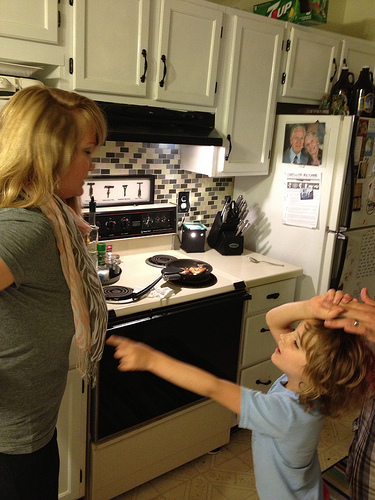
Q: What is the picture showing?
A: It is showing a kitchen.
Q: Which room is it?
A: It is a kitchen.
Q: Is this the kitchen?
A: Yes, it is the kitchen.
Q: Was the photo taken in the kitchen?
A: Yes, it was taken in the kitchen.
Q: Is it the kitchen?
A: Yes, it is the kitchen.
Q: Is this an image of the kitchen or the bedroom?
A: It is showing the kitchen.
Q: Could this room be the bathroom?
A: No, it is the kitchen.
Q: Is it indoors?
A: Yes, it is indoors.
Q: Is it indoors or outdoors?
A: It is indoors.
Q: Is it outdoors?
A: No, it is indoors.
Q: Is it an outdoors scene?
A: No, it is indoors.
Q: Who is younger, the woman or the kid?
A: The kid is younger than the woman.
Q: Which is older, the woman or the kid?
A: The woman is older than the kid.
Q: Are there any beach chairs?
A: No, there are no beach chairs.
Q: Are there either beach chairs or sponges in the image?
A: No, there are no beach chairs or sponges.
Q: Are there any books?
A: No, there are no books.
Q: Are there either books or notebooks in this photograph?
A: No, there are no books or notebooks.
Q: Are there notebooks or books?
A: No, there are no books or notebooks.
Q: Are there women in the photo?
A: Yes, there is a woman.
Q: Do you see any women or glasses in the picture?
A: Yes, there is a woman.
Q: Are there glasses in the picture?
A: No, there are no glasses.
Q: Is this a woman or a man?
A: This is a woman.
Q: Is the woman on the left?
A: Yes, the woman is on the left of the image.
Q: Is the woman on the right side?
A: No, the woman is on the left of the image.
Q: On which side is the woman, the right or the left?
A: The woman is on the left of the image.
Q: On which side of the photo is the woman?
A: The woman is on the left of the image.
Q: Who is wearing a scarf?
A: The woman is wearing a scarf.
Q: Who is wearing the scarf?
A: The woman is wearing a scarf.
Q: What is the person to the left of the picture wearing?
A: The woman is wearing a scarf.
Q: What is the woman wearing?
A: The woman is wearing a scarf.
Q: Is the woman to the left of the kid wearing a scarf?
A: Yes, the woman is wearing a scarf.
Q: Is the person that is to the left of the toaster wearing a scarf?
A: Yes, the woman is wearing a scarf.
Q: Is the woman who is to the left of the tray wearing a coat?
A: No, the woman is wearing a scarf.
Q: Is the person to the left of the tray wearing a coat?
A: No, the woman is wearing a scarf.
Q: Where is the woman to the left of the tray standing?
A: The woman is standing in the kitchen.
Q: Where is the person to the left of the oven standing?
A: The woman is standing in the kitchen.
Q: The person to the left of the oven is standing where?
A: The woman is standing in the kitchen.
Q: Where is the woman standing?
A: The woman is standing in the kitchen.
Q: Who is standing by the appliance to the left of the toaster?
A: The woman is standing by the oven.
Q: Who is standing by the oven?
A: The woman is standing by the oven.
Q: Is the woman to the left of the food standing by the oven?
A: Yes, the woman is standing by the oven.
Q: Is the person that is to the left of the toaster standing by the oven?
A: Yes, the woman is standing by the oven.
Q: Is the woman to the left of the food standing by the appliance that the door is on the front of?
A: Yes, the woman is standing by the oven.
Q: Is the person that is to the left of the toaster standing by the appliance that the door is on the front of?
A: Yes, the woman is standing by the oven.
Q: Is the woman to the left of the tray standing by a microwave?
A: No, the woman is standing by the oven.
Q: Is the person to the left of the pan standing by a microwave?
A: No, the woman is standing by the oven.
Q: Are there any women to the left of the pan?
A: Yes, there is a woman to the left of the pan.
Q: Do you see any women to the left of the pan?
A: Yes, there is a woman to the left of the pan.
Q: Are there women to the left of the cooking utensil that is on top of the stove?
A: Yes, there is a woman to the left of the pan.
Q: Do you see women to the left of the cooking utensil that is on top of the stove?
A: Yes, there is a woman to the left of the pan.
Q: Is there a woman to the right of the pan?
A: No, the woman is to the left of the pan.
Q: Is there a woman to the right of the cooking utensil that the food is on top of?
A: No, the woman is to the left of the pan.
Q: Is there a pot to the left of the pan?
A: No, there is a woman to the left of the pan.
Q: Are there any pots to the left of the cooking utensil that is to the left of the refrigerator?
A: No, there is a woman to the left of the pan.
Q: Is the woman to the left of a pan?
A: Yes, the woman is to the left of a pan.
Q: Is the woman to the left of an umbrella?
A: No, the woman is to the left of a pan.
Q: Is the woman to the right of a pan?
A: No, the woman is to the left of a pan.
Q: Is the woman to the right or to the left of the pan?
A: The woman is to the left of the pan.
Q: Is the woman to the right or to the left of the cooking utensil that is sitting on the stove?
A: The woman is to the left of the pan.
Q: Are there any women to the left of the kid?
A: Yes, there is a woman to the left of the kid.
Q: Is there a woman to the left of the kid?
A: Yes, there is a woman to the left of the kid.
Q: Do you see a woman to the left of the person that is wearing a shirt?
A: Yes, there is a woman to the left of the kid.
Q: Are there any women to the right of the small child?
A: No, the woman is to the left of the kid.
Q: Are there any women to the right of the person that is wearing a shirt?
A: No, the woman is to the left of the kid.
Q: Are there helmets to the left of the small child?
A: No, there is a woman to the left of the child.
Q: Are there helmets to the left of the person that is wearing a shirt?
A: No, there is a woman to the left of the child.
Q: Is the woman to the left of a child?
A: Yes, the woman is to the left of a child.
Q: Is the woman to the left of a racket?
A: No, the woman is to the left of a child.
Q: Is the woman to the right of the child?
A: No, the woman is to the left of the child.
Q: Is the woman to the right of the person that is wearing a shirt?
A: No, the woman is to the left of the child.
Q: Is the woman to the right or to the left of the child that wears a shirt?
A: The woman is to the left of the child.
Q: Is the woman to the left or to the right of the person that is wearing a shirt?
A: The woman is to the left of the child.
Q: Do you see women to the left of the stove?
A: Yes, there is a woman to the left of the stove.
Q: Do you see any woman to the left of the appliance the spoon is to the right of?
A: Yes, there is a woman to the left of the stove.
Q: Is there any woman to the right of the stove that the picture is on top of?
A: No, the woman is to the left of the stove.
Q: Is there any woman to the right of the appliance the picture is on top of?
A: No, the woman is to the left of the stove.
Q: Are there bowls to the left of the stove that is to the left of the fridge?
A: No, there is a woman to the left of the stove.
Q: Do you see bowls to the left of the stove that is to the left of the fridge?
A: No, there is a woman to the left of the stove.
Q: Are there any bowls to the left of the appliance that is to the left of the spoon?
A: No, there is a woman to the left of the stove.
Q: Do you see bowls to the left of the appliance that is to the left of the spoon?
A: No, there is a woman to the left of the stove.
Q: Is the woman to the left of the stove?
A: Yes, the woman is to the left of the stove.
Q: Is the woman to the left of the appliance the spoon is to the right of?
A: Yes, the woman is to the left of the stove.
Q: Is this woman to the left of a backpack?
A: No, the woman is to the left of the stove.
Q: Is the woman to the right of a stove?
A: No, the woman is to the left of a stove.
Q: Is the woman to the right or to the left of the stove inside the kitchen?
A: The woman is to the left of the stove.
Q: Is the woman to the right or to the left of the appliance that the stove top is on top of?
A: The woman is to the left of the stove.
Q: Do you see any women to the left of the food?
A: Yes, there is a woman to the left of the food.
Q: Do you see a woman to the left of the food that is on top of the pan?
A: Yes, there is a woman to the left of the food.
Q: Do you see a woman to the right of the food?
A: No, the woman is to the left of the food.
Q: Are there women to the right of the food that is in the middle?
A: No, the woman is to the left of the food.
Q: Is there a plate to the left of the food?
A: No, there is a woman to the left of the food.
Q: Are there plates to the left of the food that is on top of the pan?
A: No, there is a woman to the left of the food.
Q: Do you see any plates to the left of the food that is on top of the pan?
A: No, there is a woman to the left of the food.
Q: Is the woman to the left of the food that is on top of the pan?
A: Yes, the woman is to the left of the food.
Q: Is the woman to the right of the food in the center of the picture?
A: No, the woman is to the left of the food.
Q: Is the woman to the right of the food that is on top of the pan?
A: No, the woman is to the left of the food.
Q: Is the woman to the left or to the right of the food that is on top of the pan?
A: The woman is to the left of the food.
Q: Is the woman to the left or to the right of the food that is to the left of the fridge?
A: The woman is to the left of the food.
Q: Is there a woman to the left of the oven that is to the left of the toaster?
A: Yes, there is a woman to the left of the oven.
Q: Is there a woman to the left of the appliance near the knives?
A: Yes, there is a woman to the left of the oven.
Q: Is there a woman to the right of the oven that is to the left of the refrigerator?
A: No, the woman is to the left of the oven.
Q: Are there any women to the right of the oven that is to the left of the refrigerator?
A: No, the woman is to the left of the oven.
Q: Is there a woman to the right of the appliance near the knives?
A: No, the woman is to the left of the oven.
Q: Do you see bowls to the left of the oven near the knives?
A: No, there is a woman to the left of the oven.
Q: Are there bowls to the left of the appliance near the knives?
A: No, there is a woman to the left of the oven.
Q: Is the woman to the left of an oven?
A: Yes, the woman is to the left of an oven.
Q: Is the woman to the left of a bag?
A: No, the woman is to the left of an oven.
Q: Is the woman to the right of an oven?
A: No, the woman is to the left of an oven.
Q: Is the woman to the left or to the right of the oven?
A: The woman is to the left of the oven.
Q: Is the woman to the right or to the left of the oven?
A: The woman is to the left of the oven.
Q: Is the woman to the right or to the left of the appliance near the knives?
A: The woman is to the left of the oven.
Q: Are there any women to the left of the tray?
A: Yes, there is a woman to the left of the tray.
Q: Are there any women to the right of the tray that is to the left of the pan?
A: No, the woman is to the left of the tray.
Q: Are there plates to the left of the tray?
A: No, there is a woman to the left of the tray.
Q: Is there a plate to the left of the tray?
A: No, there is a woman to the left of the tray.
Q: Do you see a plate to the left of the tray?
A: No, there is a woman to the left of the tray.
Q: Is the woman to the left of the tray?
A: Yes, the woman is to the left of the tray.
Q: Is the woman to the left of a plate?
A: No, the woman is to the left of the tray.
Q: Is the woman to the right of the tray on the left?
A: No, the woman is to the left of the tray.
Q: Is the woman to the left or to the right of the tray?
A: The woman is to the left of the tray.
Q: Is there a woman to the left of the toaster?
A: Yes, there is a woman to the left of the toaster.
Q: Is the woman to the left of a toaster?
A: Yes, the woman is to the left of a toaster.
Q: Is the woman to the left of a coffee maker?
A: No, the woman is to the left of a toaster.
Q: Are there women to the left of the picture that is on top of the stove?
A: Yes, there is a woman to the left of the picture.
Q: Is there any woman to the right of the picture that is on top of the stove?
A: No, the woman is to the left of the picture.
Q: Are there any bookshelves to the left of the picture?
A: No, there is a woman to the left of the picture.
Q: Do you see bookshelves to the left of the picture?
A: No, there is a woman to the left of the picture.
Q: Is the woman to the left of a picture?
A: Yes, the woman is to the left of a picture.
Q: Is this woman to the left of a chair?
A: No, the woman is to the left of a picture.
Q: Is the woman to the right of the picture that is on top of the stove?
A: No, the woman is to the left of the picture.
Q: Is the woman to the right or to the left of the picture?
A: The woman is to the left of the picture.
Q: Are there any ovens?
A: Yes, there is an oven.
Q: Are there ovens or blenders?
A: Yes, there is an oven.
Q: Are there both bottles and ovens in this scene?
A: Yes, there are both an oven and a bottle.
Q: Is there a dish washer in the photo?
A: No, there are no dishwashers.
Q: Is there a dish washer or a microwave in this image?
A: No, there are no dishwashers or microwaves.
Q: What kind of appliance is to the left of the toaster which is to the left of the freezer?
A: The appliance is an oven.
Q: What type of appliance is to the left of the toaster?
A: The appliance is an oven.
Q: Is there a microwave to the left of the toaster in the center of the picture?
A: No, there is an oven to the left of the toaster.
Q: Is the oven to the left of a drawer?
A: No, the oven is to the left of the toaster.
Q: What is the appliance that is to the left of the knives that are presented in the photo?
A: The appliance is an oven.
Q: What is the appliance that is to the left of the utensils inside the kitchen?
A: The appliance is an oven.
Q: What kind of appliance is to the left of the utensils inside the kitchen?
A: The appliance is an oven.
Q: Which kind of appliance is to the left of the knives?
A: The appliance is an oven.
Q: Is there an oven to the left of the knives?
A: Yes, there is an oven to the left of the knives.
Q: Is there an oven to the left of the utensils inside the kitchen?
A: Yes, there is an oven to the left of the knives.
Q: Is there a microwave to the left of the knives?
A: No, there is an oven to the left of the knives.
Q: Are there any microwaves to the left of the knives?
A: No, there is an oven to the left of the knives.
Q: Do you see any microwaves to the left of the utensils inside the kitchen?
A: No, there is an oven to the left of the knives.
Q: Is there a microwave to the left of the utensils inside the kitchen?
A: No, there is an oven to the left of the knives.